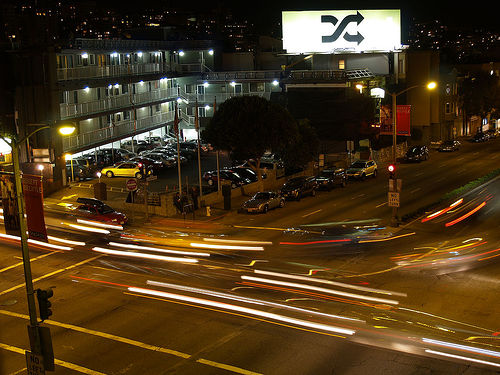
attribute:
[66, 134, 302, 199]
lot — well lit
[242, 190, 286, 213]
car — gray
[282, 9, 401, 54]
sign — lit, large, white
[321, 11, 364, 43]
arrow — black, obscure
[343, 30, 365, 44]
arrow — black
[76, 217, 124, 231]
light — whizzing by, bright, fast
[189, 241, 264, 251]
light — whizzing by, bright, fast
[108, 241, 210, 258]
light — whizzing by, bright, fast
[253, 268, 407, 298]
light — whizzing by, bright, fast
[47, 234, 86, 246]
light — whizzing by, bright, fast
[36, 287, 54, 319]
traffic light — black metal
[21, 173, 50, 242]
banner — red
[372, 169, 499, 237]
island — thin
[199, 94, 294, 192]
tree — bushy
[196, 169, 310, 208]
wall — low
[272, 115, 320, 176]
tree — bushy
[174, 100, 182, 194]
pole — tall, white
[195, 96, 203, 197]
pole — tall, white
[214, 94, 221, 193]
pole — tall, white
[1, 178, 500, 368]
traffic — time lapse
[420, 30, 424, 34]
city light — dim, background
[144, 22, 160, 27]
city light — dim, background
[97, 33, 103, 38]
city light — dim, background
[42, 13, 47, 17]
city light — dim, background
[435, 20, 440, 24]
city light — dim, background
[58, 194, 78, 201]
arrow — white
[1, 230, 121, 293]
pedestrian crosswalk — yellow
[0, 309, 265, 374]
pedestrian crosswalk — yellow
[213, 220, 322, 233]
pedestrian crosswalk — yellow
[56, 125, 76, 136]
street lamp — lit, lonely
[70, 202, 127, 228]
car — red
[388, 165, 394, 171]
light — red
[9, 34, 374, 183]
building — hotel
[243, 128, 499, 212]
row — of parked cars